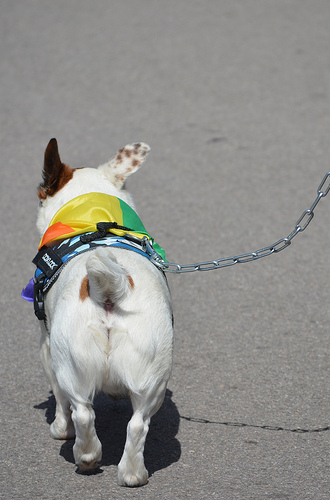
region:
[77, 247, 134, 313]
the tail of the dog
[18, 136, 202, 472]
a brown and white dog walking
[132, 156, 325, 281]
the chain leash on the dog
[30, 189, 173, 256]
the yellow and green bandana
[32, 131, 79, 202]
the brown ear of the dog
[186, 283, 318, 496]
the pavement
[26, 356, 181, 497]
the legs of the dog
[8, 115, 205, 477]
a dog walking on a leash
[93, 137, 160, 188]
the brown spotted ear of the dog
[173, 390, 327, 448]
the shadow of the chain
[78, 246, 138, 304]
tail of a dog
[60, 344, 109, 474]
leg of a dog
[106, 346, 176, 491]
leg of a dog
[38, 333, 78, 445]
leg of a dog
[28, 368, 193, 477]
shadow of a dog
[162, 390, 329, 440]
shadow of the dog's chain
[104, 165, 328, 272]
silver chain used as a leash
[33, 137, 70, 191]
ear of a dog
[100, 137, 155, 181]
ear of a dog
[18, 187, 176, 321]
colorful jacket on a dog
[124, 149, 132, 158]
brown spot on dogs ear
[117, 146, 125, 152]
brown spot on dogs ear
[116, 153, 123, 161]
brown spot on dogs ear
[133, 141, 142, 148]
brown spot on dogs ear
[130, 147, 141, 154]
brown spot on dogs ear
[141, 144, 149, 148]
brown spot on dogs ear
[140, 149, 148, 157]
brown spot on dogs ear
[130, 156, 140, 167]
brown spot on dogs ear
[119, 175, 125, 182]
brown spot on dogs ear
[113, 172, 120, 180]
brown spot on dogs ear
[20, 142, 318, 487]
a small dog going for a walk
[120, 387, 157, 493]
the leg of a dog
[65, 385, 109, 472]
the leg of a dog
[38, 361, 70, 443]
the leg of a dog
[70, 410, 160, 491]
the rear legs of a dog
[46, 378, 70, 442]
the front leg of a dog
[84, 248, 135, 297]
the tail of a dog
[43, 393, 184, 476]
the shadow of a dog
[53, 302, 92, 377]
the fur of a dog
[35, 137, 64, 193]
the ear of a dog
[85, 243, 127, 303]
the white tail on the dog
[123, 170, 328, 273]
the chain connected the dog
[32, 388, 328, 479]
the shadow on the ground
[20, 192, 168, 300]
the fabric on the dog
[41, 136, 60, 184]
the brown ear on the dog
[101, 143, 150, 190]
the white ear with brown spots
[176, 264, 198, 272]
the link on the chain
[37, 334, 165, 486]
the dog's legs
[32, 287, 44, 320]
the plastic buckle on the dog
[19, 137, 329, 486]
the dog walking and connected to a chain